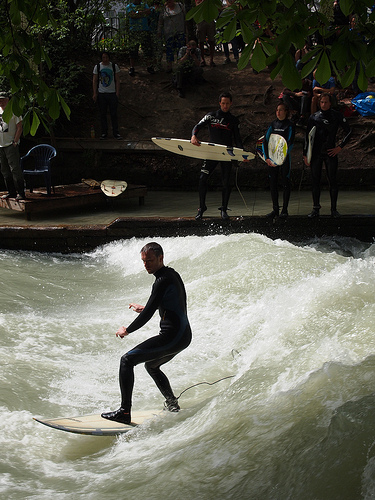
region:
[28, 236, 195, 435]
A MAN IS SKIING ON SKATEBOARD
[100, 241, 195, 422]
THE MAN DRESS IN BLACK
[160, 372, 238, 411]
THE MAN HAS A ROPE TIE TO HIS ANKLE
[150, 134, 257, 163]
THE MAN IS HOLDING THE SKATEBOARD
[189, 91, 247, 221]
THE MAN IS DRESS IN BLACK RED AND WHITE WRITING ON IT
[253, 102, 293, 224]
LADY DRESS IN BLUE AND BLACK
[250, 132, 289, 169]
LADY IS HOLDING A SMALL ROUND BOARD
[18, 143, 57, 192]
THERE IS A DARK CHAIR SITTING ON A LOW TABLE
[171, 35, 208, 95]
A MAN IS TAKING PICTURES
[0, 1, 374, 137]
THERE IS LOT OF TREES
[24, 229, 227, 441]
man on surf board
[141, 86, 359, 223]
three people watching surfer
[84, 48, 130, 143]
man in suspenders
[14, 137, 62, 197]
blue chair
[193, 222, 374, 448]
the water is agitated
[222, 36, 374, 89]
big leaves on tropical tree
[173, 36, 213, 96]
man sitting in the background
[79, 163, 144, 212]
surf board available to ride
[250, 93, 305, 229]
the only woman in the picture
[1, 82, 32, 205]
partially seen man with hand in pocket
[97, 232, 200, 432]
a surfer wearing a wet suit in the water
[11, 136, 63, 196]
a blue chair next to the surfing area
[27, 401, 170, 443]
a white surfboard in the water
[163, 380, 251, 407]
a string tied around the surfer's ankle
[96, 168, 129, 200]
a white surfboard out of the water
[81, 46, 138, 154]
a man with a white shirt watching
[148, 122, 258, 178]
a white surfboard being held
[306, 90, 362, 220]
a man watching the surfing and holding a surfboard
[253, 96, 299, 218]
a woman standing on shore waiting to surf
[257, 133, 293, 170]
a white surf board the lady is holding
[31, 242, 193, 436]
Surfer on a surfboard.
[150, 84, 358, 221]
Three surfers standing together.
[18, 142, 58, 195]
Plastic chair.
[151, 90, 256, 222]
Male surfer holding a board.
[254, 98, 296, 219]
Surfer wearing a black and blue wetsuit.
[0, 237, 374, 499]
Water being used for surfing.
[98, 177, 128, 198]
Surfboard.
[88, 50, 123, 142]
Person watching a surfer.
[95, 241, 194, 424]
Surfer in a black wetsuit.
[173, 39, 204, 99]
Person sitting talking on a cell phone.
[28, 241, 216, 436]
a man on a surfboard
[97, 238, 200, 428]
a surfer wearing a wetsuit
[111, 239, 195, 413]
a surfer has his hair wet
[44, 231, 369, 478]
a large wave behind surfer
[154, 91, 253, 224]
a man holding a surfboard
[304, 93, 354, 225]
a surfer with his hand on hip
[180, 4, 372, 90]
many green leaves hanging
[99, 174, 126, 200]
a surfboard laying flat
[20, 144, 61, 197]
a plastic blue chair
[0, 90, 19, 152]
a man wearing a white t-shirt